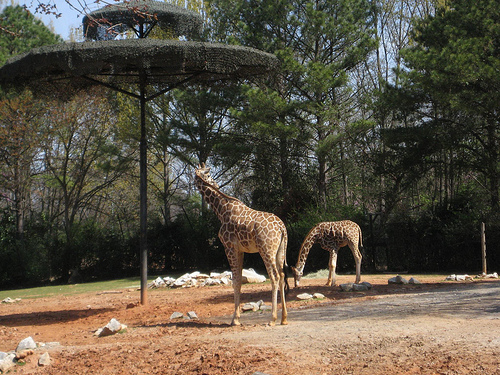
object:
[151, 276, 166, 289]
rocks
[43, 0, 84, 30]
sky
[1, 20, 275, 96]
structure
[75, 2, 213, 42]
tiers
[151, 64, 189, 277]
trees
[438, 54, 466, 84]
tree leaves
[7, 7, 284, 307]
object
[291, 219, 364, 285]
giraffe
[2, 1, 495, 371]
photo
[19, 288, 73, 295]
grass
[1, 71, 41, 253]
tree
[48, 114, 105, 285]
tree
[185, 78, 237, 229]
tree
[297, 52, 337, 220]
tree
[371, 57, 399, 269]
tree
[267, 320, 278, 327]
hoof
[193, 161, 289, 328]
giraffe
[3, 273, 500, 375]
ground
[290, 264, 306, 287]
head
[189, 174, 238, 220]
neck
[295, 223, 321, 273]
neck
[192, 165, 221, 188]
head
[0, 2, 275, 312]
umbrella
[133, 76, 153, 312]
pole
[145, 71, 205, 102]
support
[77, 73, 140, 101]
support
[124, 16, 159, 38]
support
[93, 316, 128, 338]
stones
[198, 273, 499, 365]
path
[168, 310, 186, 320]
stones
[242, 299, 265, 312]
stones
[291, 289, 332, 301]
stones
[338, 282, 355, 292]
stones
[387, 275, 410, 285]
stones